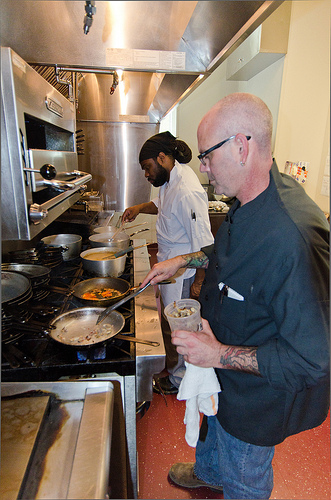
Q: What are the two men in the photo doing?
A: Cooking.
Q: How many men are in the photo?
A: Two.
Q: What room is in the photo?
A: Kitchen.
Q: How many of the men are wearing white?
A: One.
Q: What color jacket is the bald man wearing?
A: Blue.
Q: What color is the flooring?
A: Red.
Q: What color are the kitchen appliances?
A: Silver.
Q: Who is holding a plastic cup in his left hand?
A: Bald man.